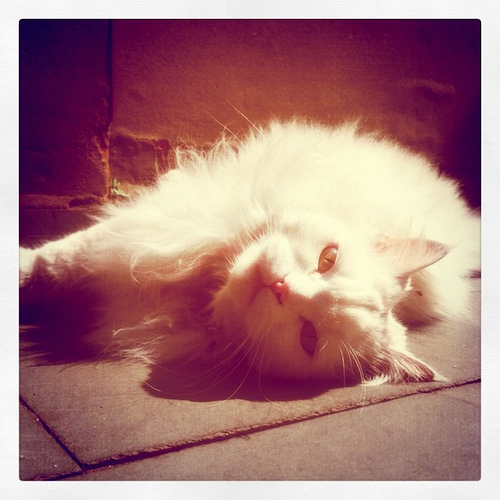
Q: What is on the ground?
A: A shadow.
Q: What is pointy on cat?
A: Ears.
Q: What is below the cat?
A: A mat.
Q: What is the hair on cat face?
A: Whiskers.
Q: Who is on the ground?
A: White cat.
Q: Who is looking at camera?
A: Cat.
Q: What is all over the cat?
A: White fur.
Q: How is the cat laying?
A: On side.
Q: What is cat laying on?
A: Rug.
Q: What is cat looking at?
A: Camera.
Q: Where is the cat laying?
A: Rug.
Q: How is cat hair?
A: Sticking out.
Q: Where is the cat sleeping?
A: Rug.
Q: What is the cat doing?
A: Laying.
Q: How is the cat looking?
A: Fluffy.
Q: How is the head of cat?
A: Sideway.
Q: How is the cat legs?
A: White.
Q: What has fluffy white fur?
A: The cat.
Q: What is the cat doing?
A: Lying down.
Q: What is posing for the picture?
A: This cat.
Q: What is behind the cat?
A: Brown background.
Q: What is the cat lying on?
A: Tile.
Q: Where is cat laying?
A: On floor.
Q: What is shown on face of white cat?
A: Whiskers.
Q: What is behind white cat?
A: Wall.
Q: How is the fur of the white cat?
A: Fuzzy.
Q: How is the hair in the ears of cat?
A: White.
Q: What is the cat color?
A: White.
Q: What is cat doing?
A: Laying down.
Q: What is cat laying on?
A: Rug.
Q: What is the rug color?
A: Brown.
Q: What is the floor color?
A: Grey.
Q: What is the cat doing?
A: Lying down.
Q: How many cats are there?
A: One.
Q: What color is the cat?
A: White.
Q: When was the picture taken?
A: Daytime.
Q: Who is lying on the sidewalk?
A: A cat.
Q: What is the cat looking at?
A: Camera.